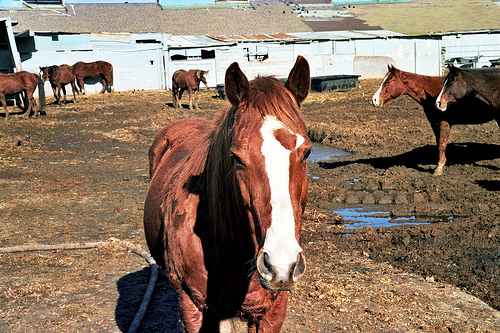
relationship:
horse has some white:
[143, 55, 315, 331] [257, 113, 307, 291]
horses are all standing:
[0, 60, 499, 331] [0, 58, 499, 332]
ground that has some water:
[0, 78, 499, 332] [300, 131, 470, 239]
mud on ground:
[1, 79, 499, 331] [0, 78, 499, 332]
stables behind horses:
[0, 0, 498, 99] [0, 60, 499, 331]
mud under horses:
[1, 79, 499, 331] [0, 60, 499, 331]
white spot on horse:
[257, 113, 307, 291] [143, 55, 315, 331]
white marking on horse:
[257, 113, 307, 291] [143, 55, 315, 331]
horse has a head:
[143, 55, 315, 331] [225, 55, 315, 292]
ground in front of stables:
[0, 78, 499, 332] [0, 0, 498, 99]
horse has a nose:
[143, 55, 315, 331] [257, 248, 306, 284]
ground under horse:
[0, 78, 499, 332] [143, 55, 315, 331]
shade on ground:
[2, 91, 500, 331] [0, 78, 499, 332]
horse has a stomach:
[143, 55, 315, 331] [143, 221, 168, 274]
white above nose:
[257, 113, 307, 291] [257, 248, 306, 284]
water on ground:
[300, 131, 470, 239] [0, 78, 499, 332]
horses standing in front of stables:
[0, 60, 499, 331] [0, 0, 498, 99]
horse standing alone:
[143, 55, 315, 331] [143, 55, 309, 332]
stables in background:
[0, 0, 498, 99] [0, 0, 499, 111]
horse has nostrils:
[143, 55, 315, 331] [259, 249, 308, 283]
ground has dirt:
[0, 78, 499, 332] [0, 78, 499, 332]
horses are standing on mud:
[0, 60, 499, 331] [1, 79, 499, 331]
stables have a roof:
[0, 0, 498, 99] [0, 0, 498, 45]